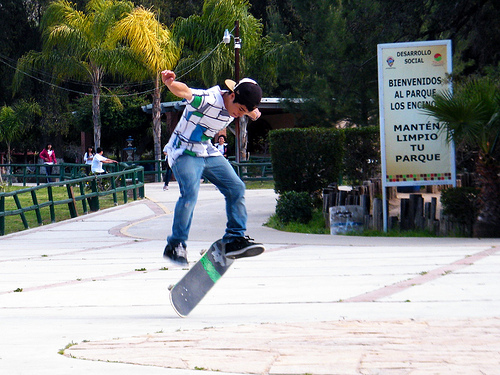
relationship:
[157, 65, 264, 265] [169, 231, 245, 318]
boy over skateboard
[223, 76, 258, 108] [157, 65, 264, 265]
baseball cap on head of boy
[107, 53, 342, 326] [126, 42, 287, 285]
shirt on boy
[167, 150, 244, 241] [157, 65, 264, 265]
blue jeans. on boy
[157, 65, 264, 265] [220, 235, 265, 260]
boy wearing black shoes black shoe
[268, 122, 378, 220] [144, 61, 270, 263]
bushes behind boy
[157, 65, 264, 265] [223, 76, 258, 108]
boy wears baseball cap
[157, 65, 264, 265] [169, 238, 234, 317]
boy jumps on skateboard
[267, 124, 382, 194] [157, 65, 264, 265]
hedge behind boy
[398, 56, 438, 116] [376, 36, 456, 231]
part of board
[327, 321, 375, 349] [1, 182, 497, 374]
part of floor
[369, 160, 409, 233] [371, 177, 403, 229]
part of stand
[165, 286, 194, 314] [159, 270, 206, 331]
edge of board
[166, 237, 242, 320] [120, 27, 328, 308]
board in air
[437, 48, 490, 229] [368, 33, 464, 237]
palm tree by sign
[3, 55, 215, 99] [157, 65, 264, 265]
power lines behind boy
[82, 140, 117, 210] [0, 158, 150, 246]
person near a fence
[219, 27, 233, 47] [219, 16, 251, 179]
light on a pole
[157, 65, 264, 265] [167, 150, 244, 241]
boy has blue jeans.